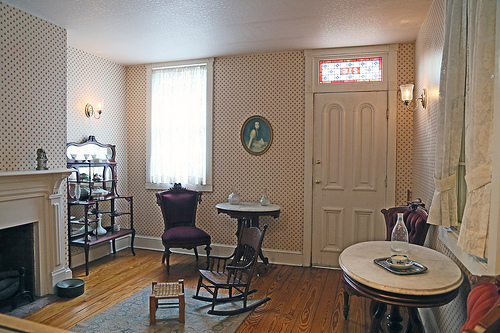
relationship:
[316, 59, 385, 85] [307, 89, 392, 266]
window above door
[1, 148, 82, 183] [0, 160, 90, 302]
mantle above fire place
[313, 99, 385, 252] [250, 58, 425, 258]
white door on wall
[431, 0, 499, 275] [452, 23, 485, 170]
curtain around aa window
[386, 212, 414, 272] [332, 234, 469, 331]
glass bottle on a table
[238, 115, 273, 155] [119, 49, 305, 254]
picture on wall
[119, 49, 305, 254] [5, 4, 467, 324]
wall in room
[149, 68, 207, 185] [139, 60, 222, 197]
curtain on window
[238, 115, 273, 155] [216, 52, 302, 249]
picture on wall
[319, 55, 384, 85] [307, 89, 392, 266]
glass above door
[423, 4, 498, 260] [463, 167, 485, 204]
curtain has tie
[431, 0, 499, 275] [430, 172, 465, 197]
curtain has curtain tie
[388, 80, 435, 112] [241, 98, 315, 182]
light on wall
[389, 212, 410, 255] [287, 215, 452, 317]
glass bottle on table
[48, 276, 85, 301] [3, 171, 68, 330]
black object next to fireplace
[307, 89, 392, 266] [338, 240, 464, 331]
door next to table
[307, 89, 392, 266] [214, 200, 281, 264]
door next to table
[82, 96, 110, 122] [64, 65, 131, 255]
lamp mounted on wall